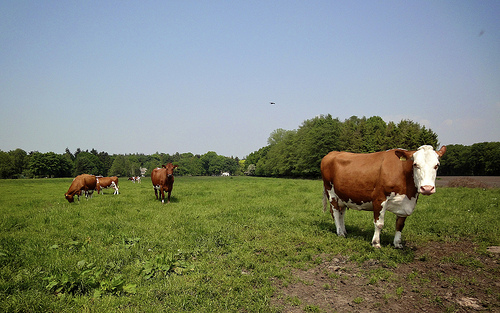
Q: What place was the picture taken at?
A: It was taken at the field.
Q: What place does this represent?
A: It represents the field.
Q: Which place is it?
A: It is a field.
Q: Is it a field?
A: Yes, it is a field.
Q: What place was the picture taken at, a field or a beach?
A: It was taken at a field.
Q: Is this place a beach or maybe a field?
A: It is a field.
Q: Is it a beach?
A: No, it is a field.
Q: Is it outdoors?
A: Yes, it is outdoors.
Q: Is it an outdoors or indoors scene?
A: It is outdoors.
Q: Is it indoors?
A: No, it is outdoors.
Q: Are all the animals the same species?
A: Yes, all the animals are cows.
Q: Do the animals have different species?
A: No, all the animals are cows.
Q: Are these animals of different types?
A: No, all the animals are cows.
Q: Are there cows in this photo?
A: Yes, there is a cow.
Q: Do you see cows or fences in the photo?
A: Yes, there is a cow.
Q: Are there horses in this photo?
A: No, there are no horses.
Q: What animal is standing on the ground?
A: The cow is standing on the ground.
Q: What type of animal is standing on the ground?
A: The animal is a cow.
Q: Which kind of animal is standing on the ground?
A: The animal is a cow.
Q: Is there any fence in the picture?
A: No, there are no fences.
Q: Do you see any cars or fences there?
A: No, there are no fences or cars.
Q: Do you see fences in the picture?
A: No, there are no fences.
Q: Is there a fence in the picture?
A: No, there are no fences.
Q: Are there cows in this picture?
A: Yes, there is a cow.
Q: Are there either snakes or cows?
A: Yes, there is a cow.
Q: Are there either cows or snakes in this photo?
A: Yes, there is a cow.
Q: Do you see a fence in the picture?
A: No, there are no fences.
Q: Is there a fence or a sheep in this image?
A: No, there are no fences or sheep.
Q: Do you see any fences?
A: No, there are no fences.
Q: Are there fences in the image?
A: No, there are no fences.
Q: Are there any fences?
A: No, there are no fences.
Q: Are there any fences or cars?
A: No, there are no fences or cars.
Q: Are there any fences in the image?
A: No, there are no fences.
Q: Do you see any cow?
A: Yes, there is a cow.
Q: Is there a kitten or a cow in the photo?
A: Yes, there is a cow.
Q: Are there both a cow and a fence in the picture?
A: No, there is a cow but no fences.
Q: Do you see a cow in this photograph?
A: Yes, there is a cow.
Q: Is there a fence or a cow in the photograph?
A: Yes, there is a cow.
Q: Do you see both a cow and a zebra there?
A: No, there is a cow but no zebras.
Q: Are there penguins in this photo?
A: No, there are no penguins.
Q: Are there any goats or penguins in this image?
A: No, there are no penguins or goats.